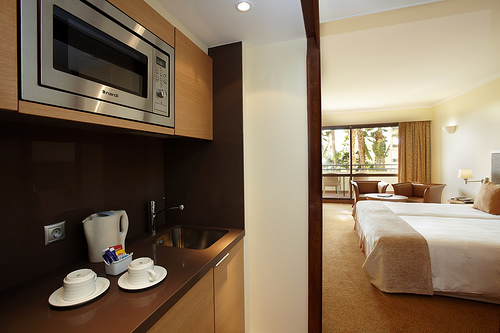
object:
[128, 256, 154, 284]
cup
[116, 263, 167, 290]
plate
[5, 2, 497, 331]
hotel room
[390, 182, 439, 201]
chair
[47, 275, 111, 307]
saucer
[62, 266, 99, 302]
mug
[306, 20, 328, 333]
framing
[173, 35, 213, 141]
cabinet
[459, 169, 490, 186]
lamp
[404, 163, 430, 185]
ground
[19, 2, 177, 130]
metal microwave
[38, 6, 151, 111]
door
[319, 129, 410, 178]
window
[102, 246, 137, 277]
caddy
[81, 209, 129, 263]
white pitcher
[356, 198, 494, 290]
blanket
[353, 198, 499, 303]
bed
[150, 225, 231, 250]
sink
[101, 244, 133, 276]
holder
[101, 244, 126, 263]
packets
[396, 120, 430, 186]
curtain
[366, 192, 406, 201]
table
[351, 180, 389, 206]
chairs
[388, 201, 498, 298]
bedspread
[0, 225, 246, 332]
countertop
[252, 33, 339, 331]
wall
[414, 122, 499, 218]
wall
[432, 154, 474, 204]
shade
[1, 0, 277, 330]
mini kitchen